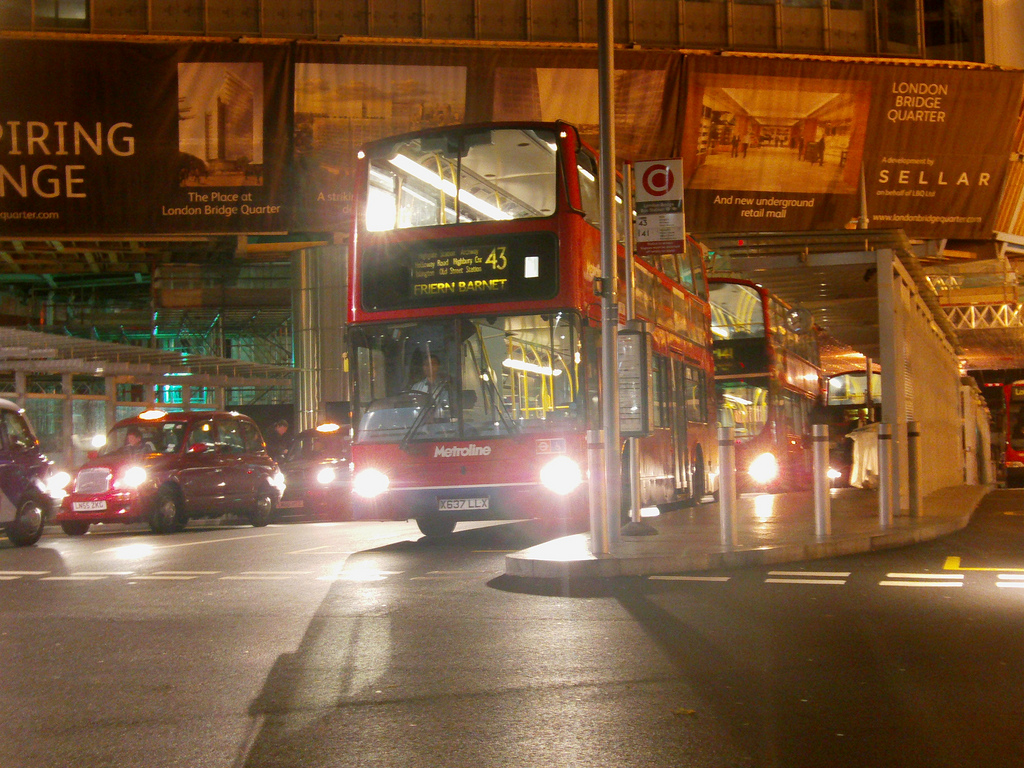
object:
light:
[539, 456, 585, 497]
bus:
[57, 409, 289, 539]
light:
[139, 409, 167, 420]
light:
[525, 256, 542, 278]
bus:
[340, 116, 847, 546]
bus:
[687, 260, 879, 497]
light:
[747, 451, 783, 486]